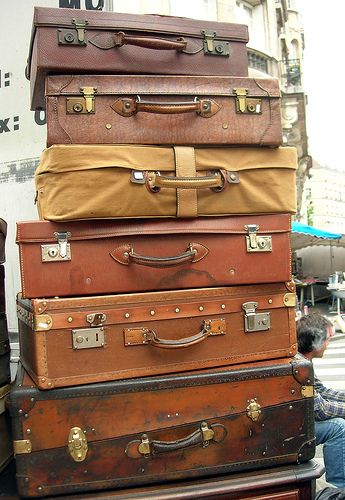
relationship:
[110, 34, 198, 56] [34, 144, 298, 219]
handle on case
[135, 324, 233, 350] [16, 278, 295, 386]
handle on case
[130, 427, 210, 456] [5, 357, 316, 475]
handle on brown case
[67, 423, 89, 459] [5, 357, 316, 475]
gold latch on brown case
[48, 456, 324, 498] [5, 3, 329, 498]
stand holding suitcases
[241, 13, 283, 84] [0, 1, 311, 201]
balcony on side of building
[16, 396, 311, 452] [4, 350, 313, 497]
diaganol line on luggage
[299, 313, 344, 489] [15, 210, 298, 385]
man next to cases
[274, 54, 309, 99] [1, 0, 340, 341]
balcony on building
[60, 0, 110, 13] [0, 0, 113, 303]
black letters are on wall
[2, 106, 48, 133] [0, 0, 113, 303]
black letters are on wall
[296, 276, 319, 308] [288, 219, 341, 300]
tables are under canopy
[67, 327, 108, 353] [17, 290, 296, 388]
metal hook on suitcase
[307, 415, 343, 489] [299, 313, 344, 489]
jeans are on man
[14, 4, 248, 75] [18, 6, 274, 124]
case on top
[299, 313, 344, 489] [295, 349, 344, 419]
man wearing shirt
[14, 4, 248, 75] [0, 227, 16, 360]
case piled on table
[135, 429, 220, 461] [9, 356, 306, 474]
handle on case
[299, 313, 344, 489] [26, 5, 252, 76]
man sitting near suitcase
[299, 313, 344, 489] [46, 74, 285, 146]
man sitting near cases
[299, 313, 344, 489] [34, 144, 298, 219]
man sitting near case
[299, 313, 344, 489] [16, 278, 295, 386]
man sitting near case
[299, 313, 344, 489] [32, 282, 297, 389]
man sitting near suitcase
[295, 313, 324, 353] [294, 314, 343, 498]
hair of man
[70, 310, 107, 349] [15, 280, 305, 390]
lock on suitcase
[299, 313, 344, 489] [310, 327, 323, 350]
man has grey hair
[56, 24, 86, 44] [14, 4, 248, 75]
lock on case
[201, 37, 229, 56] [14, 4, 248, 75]
lock on case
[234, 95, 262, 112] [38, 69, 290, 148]
lock on suitcase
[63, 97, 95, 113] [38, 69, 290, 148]
lock on suitcase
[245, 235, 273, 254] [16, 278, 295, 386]
lock on case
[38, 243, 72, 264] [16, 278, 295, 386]
lock on case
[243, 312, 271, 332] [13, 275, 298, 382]
lock on suitcase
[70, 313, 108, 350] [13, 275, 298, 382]
lock on suitcase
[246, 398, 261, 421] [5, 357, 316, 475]
lock on brown case